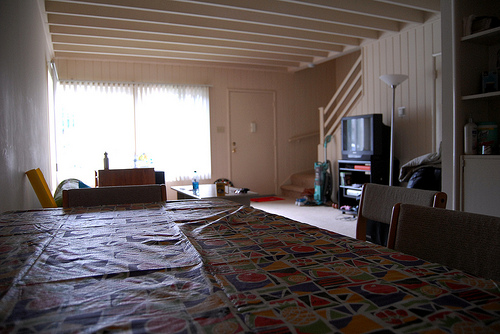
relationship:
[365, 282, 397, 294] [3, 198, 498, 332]
pattern on tablecloth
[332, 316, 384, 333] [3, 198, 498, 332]
pattern on tablecloth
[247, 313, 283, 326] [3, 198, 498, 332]
pattern on tablecloth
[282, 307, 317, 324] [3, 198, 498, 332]
pattern on tablecloth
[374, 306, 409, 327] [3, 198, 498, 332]
pattern on tablecloth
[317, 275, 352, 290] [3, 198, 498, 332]
pattern on tablecloth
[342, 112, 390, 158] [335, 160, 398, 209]
tv on stand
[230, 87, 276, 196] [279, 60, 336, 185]
door matches wall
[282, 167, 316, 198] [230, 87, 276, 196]
stairs beside door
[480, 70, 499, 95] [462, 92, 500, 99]
item on shelf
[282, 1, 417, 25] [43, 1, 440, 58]
beam on holding ceiling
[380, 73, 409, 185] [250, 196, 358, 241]
lamp on floor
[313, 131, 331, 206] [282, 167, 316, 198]
vaccum beside stairs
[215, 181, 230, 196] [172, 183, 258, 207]
item on coffee table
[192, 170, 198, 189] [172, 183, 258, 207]
bottle on coffee table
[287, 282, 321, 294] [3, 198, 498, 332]
rectangle on tablecloth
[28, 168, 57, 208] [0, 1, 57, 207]
yellow piece on wall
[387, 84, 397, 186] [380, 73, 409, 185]
pole of lamp